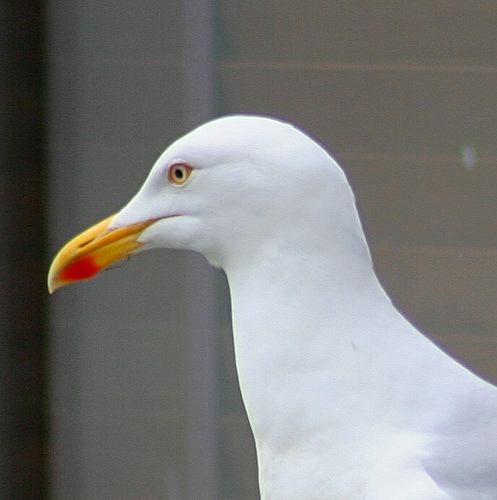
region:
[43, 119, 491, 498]
A white seagull with an orange beak and wide eye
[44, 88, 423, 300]
A Seagull with an orange beak and white feathers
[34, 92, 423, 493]
A seagull bird with white feathers is standing next to a grey structure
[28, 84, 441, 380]
The head of a white Seagul bird with yellow eye and orange beak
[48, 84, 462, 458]
A white feathered bird with an orange beak and yellow eyes is looking at the camera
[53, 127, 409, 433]
A side profile of a Seagull with yellow eyes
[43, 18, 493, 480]
The white Seagull is standing next to a grey structure in background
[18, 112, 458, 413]
A white featured Seagull is smiling at the camera with his orange beak and yellow eyes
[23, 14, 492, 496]
A Seagull with yellow eyes is poising for the camera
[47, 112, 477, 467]
The Seagull has white feathers and his yellow eyes are wide open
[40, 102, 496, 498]
the bird is white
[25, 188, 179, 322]
the bird's beak is yellow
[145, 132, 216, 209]
the bird has an eye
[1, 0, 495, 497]
the background is blurry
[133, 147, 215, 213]
the bird's eye is orange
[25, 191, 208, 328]
the bird's beak is closed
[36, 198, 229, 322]
the bird's beak has a red spot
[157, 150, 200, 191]
the bird's pupil is black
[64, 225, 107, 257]
the beak has a hole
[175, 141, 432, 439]
the bird has a long neck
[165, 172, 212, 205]
Bird has yellow eye.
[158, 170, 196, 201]
Bird has large round pupil.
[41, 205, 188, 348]
Bird's beak is mostly orange.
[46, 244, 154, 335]
Red spot on bottom of bird's beak.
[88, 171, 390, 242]
Bird has white head.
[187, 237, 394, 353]
Bird has white neck.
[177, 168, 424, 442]
Bird has many white feathers.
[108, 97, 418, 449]
Bird is near a window.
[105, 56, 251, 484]
White frame on window behind bird.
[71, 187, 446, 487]
Large white bird standing near window.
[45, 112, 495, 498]
Bird is white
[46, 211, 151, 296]
Beak is orange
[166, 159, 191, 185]
Eye on bird is yellow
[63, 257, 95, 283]
Red marking on birds beak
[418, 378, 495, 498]
Gray fur on white bird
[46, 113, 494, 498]
Bird looking left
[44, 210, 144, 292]
Beak is curved down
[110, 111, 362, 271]
Head of bird is curved at the top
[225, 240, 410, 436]
Neck is long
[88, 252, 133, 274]
String on beak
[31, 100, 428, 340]
head of white bird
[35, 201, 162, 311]
orange beak with red leaf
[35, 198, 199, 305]
closed beak of bird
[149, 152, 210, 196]
green eye of bird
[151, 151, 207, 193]
bird with opened eye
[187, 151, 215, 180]
wrinkle near birds eye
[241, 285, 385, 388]
white neck of bird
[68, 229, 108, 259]
hole in birds beak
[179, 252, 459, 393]
white neck of bird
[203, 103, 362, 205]
smooth white head of bird